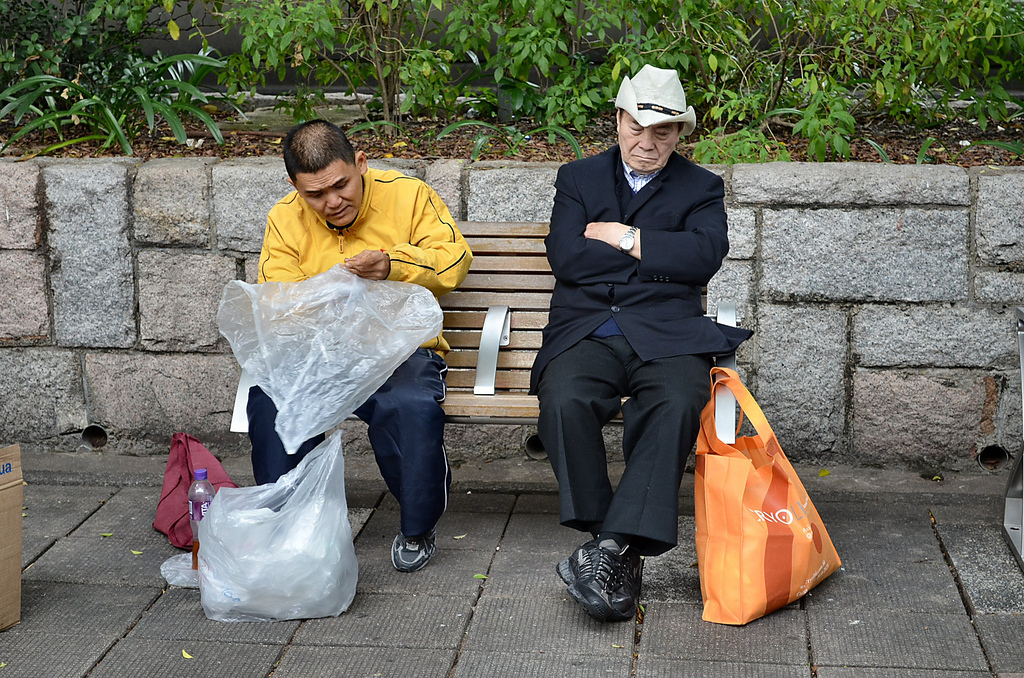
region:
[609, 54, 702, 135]
a tan cowboy hat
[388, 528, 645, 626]
the tennis shoes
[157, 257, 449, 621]
the plastic bag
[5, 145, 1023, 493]
a stoned wall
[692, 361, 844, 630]
the orange bag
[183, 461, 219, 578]
a drink on the ground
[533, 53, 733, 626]
a man in a suit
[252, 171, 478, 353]
a mustard color shirt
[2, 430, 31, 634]
a cardboard box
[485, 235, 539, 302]
The back of a wooden bench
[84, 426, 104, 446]
A drain hole in the wall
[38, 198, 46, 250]
A joint between the stone blocks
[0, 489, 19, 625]
A box sitting on the ground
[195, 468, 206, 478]
The blue cap of a bottle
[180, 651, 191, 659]
A leaf turning yellow on the ground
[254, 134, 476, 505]
hispanic man on park bench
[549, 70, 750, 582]
elderly man sitting on bench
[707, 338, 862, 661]
orange shopping back by man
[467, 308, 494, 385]
metal divider on bench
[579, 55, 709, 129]
white cowboy hat on man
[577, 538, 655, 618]
black sneakers on man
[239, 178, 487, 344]
yellow jacket on man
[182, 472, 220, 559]
water bottle by man's feet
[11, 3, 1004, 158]
green hedges on wall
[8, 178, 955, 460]
large stone bricks in wall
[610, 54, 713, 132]
Man wearing white hat.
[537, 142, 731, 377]
Man wearing dark jacket.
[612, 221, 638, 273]
Man wearing watch on wrist.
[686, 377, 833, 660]
Orange bag sitting on ground.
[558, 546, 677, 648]
Man wearing black shoes.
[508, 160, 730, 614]
Man sitting on bench.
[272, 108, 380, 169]
Man has short black hair.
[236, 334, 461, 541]
Man wearing blue pants.